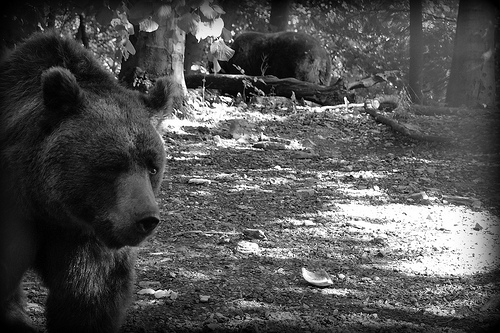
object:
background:
[181, 34, 334, 85]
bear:
[0, 28, 168, 333]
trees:
[141, 1, 194, 137]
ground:
[0, 113, 499, 333]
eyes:
[147, 167, 157, 175]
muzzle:
[110, 179, 161, 248]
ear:
[41, 65, 88, 113]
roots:
[190, 110, 218, 136]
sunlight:
[272, 187, 500, 279]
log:
[184, 71, 403, 112]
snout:
[107, 214, 160, 250]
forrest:
[0, 1, 500, 145]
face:
[49, 89, 167, 250]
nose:
[134, 211, 161, 233]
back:
[29, 22, 124, 93]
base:
[148, 75, 190, 120]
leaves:
[204, 110, 261, 136]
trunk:
[409, 6, 426, 106]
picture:
[1, 0, 498, 333]